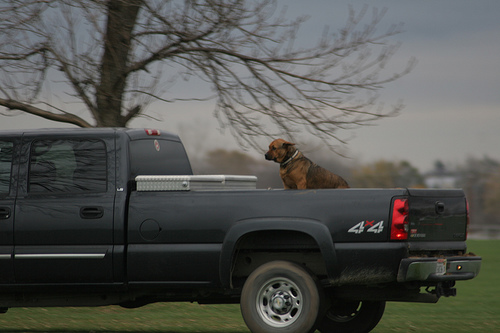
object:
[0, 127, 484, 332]
truck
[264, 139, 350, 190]
dog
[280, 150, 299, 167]
collar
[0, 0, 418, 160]
tree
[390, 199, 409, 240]
light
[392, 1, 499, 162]
sky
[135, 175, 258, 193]
box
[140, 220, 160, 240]
cover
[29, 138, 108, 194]
windows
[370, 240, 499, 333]
grass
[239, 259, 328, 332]
wheel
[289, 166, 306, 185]
brown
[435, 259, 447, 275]
plate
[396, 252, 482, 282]
bumper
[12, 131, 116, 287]
door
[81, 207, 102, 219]
handle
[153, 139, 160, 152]
sticker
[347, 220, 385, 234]
sign